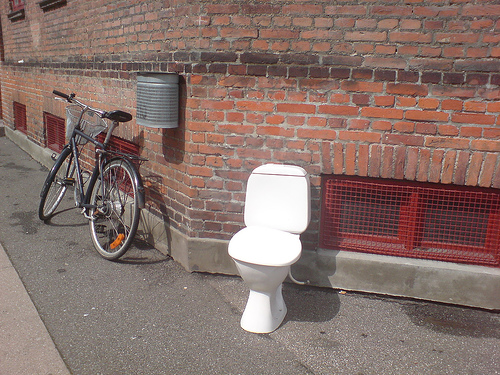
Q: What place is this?
A: It is a street.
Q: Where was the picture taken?
A: It was taken at the street.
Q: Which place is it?
A: It is a street.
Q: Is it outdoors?
A: Yes, it is outdoors.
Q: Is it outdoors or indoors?
A: It is outdoors.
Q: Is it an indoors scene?
A: No, it is outdoors.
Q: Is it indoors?
A: No, it is outdoors.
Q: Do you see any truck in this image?
A: No, there are no trucks.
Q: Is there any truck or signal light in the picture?
A: No, there are no trucks or traffic lights.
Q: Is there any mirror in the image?
A: No, there are no mirrors.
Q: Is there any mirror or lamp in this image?
A: No, there are no mirrors or lamps.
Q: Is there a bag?
A: No, there are no bags.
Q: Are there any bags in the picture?
A: No, there are no bags.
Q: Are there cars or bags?
A: No, there are no bags or cars.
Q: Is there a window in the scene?
A: Yes, there is a window.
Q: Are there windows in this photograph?
A: Yes, there is a window.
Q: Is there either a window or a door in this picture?
A: Yes, there is a window.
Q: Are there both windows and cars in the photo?
A: No, there is a window but no cars.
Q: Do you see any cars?
A: No, there are no cars.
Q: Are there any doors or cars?
A: No, there are no cars or doors.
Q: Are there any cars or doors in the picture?
A: No, there are no cars or doors.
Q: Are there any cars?
A: No, there are no cars.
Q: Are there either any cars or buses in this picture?
A: No, there are no cars or buses.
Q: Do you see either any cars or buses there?
A: No, there are no cars or buses.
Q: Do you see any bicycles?
A: Yes, there is a bicycle.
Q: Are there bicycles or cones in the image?
A: Yes, there is a bicycle.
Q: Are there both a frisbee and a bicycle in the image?
A: No, there is a bicycle but no frisbees.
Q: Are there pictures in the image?
A: No, there are no pictures.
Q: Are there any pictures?
A: No, there are no pictures.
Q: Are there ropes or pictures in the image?
A: No, there are no pictures or ropes.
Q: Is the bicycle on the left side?
A: Yes, the bicycle is on the left of the image.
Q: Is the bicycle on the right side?
A: No, the bicycle is on the left of the image.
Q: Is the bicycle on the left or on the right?
A: The bicycle is on the left of the image.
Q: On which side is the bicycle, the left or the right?
A: The bicycle is on the left of the image.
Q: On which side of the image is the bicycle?
A: The bicycle is on the left of the image.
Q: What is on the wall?
A: The bicycle is on the wall.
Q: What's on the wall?
A: The bicycle is on the wall.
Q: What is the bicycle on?
A: The bicycle is on the wall.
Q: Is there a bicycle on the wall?
A: Yes, there is a bicycle on the wall.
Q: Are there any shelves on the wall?
A: No, there is a bicycle on the wall.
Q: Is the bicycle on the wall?
A: Yes, the bicycle is on the wall.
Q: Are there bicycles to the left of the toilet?
A: Yes, there is a bicycle to the left of the toilet.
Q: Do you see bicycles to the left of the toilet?
A: Yes, there is a bicycle to the left of the toilet.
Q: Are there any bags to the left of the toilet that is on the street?
A: No, there is a bicycle to the left of the toilet.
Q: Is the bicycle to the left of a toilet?
A: Yes, the bicycle is to the left of a toilet.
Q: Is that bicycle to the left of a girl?
A: No, the bicycle is to the left of a toilet.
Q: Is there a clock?
A: No, there are no clocks.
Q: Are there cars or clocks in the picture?
A: No, there are no clocks or cars.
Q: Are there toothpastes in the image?
A: No, there are no toothpastes.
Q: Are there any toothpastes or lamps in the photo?
A: No, there are no toothpastes or lamps.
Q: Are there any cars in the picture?
A: No, there are no cars.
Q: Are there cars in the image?
A: No, there are no cars.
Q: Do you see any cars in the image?
A: No, there are no cars.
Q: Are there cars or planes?
A: No, there are no cars or planes.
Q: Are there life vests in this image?
A: No, there are no life vests.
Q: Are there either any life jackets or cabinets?
A: No, there are no life jackets or cabinets.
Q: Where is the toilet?
A: The toilet is on the street.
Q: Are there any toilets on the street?
A: Yes, there is a toilet on the street.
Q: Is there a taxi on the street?
A: No, there is a toilet on the street.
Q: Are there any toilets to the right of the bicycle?
A: Yes, there is a toilet to the right of the bicycle.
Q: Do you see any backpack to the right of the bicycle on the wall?
A: No, there is a toilet to the right of the bicycle.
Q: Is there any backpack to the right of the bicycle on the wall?
A: No, there is a toilet to the right of the bicycle.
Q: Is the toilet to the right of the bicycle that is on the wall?
A: Yes, the toilet is to the right of the bicycle.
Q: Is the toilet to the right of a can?
A: No, the toilet is to the right of the bicycle.